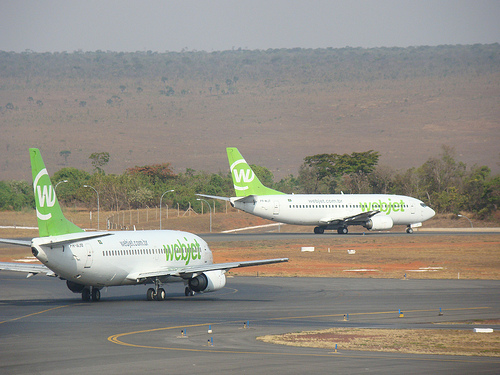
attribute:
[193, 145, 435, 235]
jet — green, white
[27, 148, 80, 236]
tail — white, green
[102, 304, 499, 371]
lines — yellow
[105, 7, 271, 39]
sky — grey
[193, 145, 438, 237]
plane — green, white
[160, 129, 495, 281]
jet — green, white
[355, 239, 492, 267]
ground — sandy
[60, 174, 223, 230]
poles — white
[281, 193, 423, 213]
windows — white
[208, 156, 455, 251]
jet — green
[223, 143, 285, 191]
tail — green, white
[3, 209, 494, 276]
sand — brown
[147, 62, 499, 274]
jet — green, white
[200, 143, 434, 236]
fuselage — large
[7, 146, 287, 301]
body — white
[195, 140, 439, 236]
body — white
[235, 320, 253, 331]
marker — blue